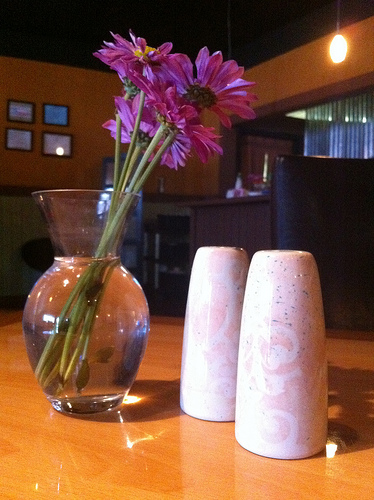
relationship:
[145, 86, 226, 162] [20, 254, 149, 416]
flower in water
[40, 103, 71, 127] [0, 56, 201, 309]
picture on wall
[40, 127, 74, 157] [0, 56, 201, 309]
picture on wall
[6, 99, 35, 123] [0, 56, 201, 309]
picture on wall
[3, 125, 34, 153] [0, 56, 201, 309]
picture on wall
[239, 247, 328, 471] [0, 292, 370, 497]
shaker on table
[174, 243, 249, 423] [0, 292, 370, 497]
shaker on table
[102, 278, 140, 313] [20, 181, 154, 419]
water in vase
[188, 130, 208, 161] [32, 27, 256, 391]
petals on flower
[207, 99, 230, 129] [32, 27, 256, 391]
petals on flower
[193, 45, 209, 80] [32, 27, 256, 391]
petals on flower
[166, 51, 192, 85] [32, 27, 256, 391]
petals on flower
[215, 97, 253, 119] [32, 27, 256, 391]
petals on flower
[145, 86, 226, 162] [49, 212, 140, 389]
flower in vase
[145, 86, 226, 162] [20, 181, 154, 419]
flower in vase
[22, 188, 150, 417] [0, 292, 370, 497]
vase on table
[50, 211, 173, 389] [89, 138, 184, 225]
vase with stems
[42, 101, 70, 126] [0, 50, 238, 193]
picture hanging on wall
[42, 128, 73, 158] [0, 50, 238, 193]
picture hanging on wall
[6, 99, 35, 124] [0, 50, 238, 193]
picture hanging on wall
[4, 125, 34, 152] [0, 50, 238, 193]
picture hanging on wall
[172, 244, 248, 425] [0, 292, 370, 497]
salt on table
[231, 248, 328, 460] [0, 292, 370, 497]
pepper on table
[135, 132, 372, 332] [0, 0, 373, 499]
bar at restaurant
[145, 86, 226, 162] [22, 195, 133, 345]
flower in vase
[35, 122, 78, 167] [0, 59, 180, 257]
frame in wall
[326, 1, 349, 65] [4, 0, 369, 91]
light hanging from ceiling